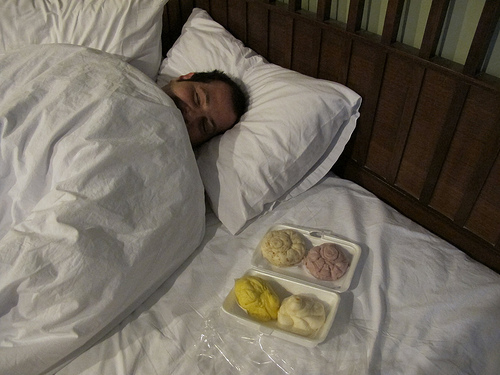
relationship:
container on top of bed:
[219, 221, 361, 346] [4, 2, 496, 372]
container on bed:
[219, 221, 361, 344] [4, 2, 496, 372]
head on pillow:
[160, 67, 248, 143] [276, 78, 370, 173]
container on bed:
[219, 221, 361, 346] [60, 163, 498, 372]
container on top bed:
[219, 221, 361, 346] [4, 2, 496, 372]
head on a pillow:
[166, 71, 248, 130] [162, 5, 369, 230]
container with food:
[219, 221, 361, 344] [302, 238, 348, 279]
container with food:
[219, 221, 361, 344] [263, 225, 309, 267]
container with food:
[219, 221, 361, 344] [283, 292, 328, 337]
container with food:
[219, 221, 361, 344] [234, 274, 274, 319]